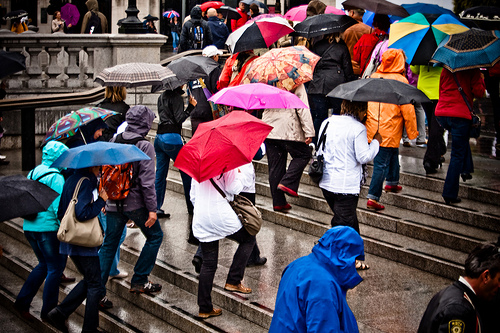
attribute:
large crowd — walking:
[1, 0, 499, 332]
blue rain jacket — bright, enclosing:
[20, 140, 69, 233]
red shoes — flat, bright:
[366, 184, 404, 209]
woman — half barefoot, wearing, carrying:
[319, 96, 381, 275]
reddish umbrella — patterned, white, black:
[174, 109, 275, 184]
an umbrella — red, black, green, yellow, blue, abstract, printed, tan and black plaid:
[199, 1, 222, 10]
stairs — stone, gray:
[1, 104, 499, 331]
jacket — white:
[318, 113, 377, 196]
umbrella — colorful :
[178, 101, 251, 172]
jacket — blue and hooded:
[283, 226, 374, 333]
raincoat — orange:
[382, 67, 407, 155]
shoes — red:
[365, 178, 403, 233]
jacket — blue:
[264, 223, 389, 333]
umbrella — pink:
[243, 100, 273, 138]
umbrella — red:
[172, 114, 287, 239]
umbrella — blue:
[52, 137, 144, 171]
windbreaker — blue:
[280, 227, 380, 333]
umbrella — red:
[181, 108, 263, 181]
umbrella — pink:
[234, 75, 302, 119]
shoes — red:
[357, 175, 404, 229]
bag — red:
[103, 150, 139, 239]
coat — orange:
[374, 54, 406, 185]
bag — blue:
[143, 136, 179, 204]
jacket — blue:
[261, 223, 374, 331]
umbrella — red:
[172, 106, 273, 183]